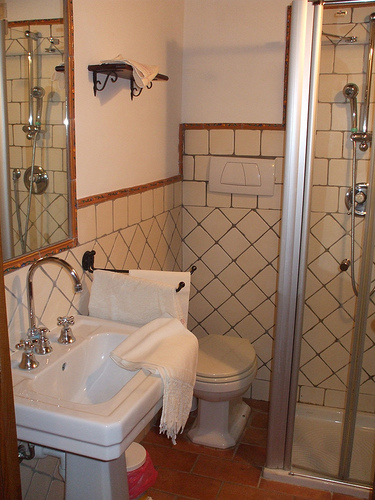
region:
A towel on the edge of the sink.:
[113, 315, 220, 447]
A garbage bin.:
[113, 443, 154, 493]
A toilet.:
[184, 322, 256, 463]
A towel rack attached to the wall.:
[75, 244, 221, 325]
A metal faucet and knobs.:
[8, 240, 92, 366]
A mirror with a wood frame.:
[0, 0, 87, 279]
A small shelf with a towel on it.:
[81, 36, 176, 117]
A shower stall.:
[259, 1, 370, 493]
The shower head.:
[331, 75, 369, 175]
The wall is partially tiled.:
[124, 98, 207, 242]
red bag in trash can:
[120, 449, 167, 498]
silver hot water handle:
[12, 330, 44, 373]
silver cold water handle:
[57, 303, 97, 360]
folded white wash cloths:
[104, 46, 166, 82]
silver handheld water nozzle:
[339, 78, 366, 188]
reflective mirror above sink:
[4, 33, 72, 176]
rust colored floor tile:
[185, 455, 255, 497]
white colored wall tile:
[211, 227, 284, 316]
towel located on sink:
[108, 328, 211, 431]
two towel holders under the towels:
[88, 248, 208, 298]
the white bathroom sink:
[9, 312, 191, 498]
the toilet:
[192, 330, 254, 450]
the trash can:
[123, 441, 155, 498]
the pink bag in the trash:
[125, 458, 157, 485]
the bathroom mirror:
[2, 1, 75, 269]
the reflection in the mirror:
[10, 10, 60, 231]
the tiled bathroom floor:
[166, 443, 245, 499]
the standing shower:
[260, 2, 373, 483]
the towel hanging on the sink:
[115, 315, 194, 443]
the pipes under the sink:
[18, 440, 68, 480]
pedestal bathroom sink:
[2, 246, 175, 498]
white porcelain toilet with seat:
[199, 321, 259, 450]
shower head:
[337, 75, 366, 135]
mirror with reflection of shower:
[4, 7, 69, 249]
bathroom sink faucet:
[13, 254, 89, 368]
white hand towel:
[109, 320, 206, 442]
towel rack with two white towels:
[80, 251, 209, 315]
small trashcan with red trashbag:
[126, 445, 162, 495]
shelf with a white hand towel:
[84, 51, 175, 104]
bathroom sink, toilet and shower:
[27, 20, 364, 495]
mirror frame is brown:
[2, 2, 89, 276]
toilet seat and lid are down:
[188, 313, 275, 406]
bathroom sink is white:
[7, 287, 239, 485]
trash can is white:
[120, 446, 161, 498]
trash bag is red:
[121, 459, 173, 498]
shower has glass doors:
[280, 9, 371, 493]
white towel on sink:
[107, 311, 230, 459]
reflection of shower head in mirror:
[3, 24, 64, 245]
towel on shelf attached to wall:
[98, 36, 184, 117]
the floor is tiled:
[151, 381, 343, 498]